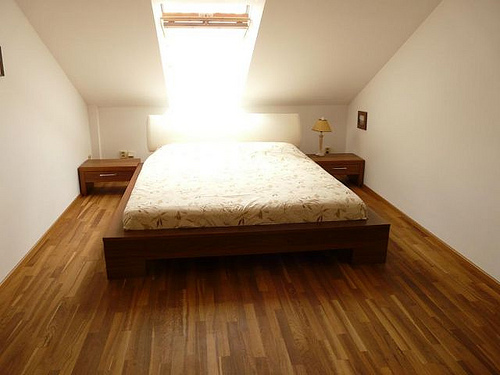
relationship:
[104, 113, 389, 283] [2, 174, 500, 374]
bed sitting on floor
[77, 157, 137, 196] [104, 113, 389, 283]
nightstand on right side of bed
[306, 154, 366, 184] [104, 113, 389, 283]
nightstand on left side of bed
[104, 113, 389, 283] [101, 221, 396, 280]
bed has footboard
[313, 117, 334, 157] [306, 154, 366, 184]
lamp sitting on nightstand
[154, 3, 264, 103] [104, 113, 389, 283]
skylight over bed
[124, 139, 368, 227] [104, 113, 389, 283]
bedspread on top of bed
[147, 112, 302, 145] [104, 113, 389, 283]
headboard on back of bed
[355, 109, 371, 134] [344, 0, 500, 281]
picture hanging on wall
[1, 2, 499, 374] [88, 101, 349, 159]
bedroom has wall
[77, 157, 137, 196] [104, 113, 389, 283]
nightstand on opposite side of bed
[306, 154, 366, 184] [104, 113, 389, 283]
nightstand on opposite side of bed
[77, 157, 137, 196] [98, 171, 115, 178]
nightstand has handle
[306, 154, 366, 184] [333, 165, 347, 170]
nightstand has handle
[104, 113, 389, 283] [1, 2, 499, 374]
bed in bedroom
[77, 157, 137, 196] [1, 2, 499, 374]
nightstand in bedroom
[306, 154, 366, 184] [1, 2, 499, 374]
nightstand in bedroom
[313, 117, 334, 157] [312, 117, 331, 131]
lamp has shade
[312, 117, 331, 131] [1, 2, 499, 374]
shade inside bedroom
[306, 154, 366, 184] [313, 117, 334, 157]
nightstand has lamp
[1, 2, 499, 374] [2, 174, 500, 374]
bedroom has floor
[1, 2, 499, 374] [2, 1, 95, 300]
bedroom has wall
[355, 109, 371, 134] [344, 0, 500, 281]
picture on side of wall